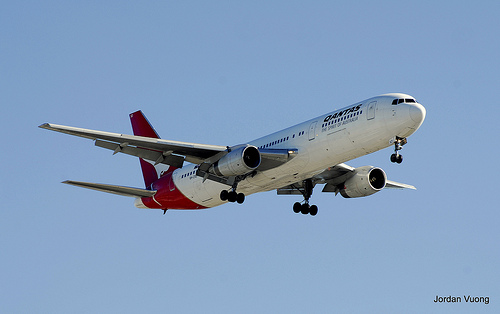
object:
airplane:
[40, 92, 425, 216]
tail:
[128, 110, 179, 189]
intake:
[243, 147, 260, 168]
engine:
[214, 145, 262, 177]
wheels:
[220, 189, 228, 200]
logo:
[323, 104, 362, 122]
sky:
[0, 0, 500, 314]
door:
[169, 174, 175, 191]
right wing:
[316, 163, 416, 190]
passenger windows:
[292, 134, 296, 138]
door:
[367, 101, 377, 120]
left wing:
[38, 123, 298, 172]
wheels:
[293, 202, 302, 213]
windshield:
[392, 99, 397, 105]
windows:
[181, 175, 183, 178]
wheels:
[391, 153, 404, 162]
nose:
[409, 103, 427, 122]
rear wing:
[60, 180, 157, 198]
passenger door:
[308, 122, 317, 141]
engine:
[339, 166, 387, 198]